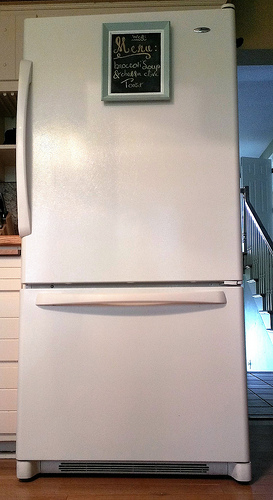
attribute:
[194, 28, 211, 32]
silver — end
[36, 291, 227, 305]
handle — white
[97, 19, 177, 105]
frame — green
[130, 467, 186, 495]
floor — dark brown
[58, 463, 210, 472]
vent — at bottom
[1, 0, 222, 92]
white cupboard —  white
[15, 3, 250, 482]
fridge — top half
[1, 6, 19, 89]
shelf — mounted up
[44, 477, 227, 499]
floor — wooden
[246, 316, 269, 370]
light — reflected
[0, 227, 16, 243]
table — wooden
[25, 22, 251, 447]
fridge — white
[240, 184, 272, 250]
rail — brown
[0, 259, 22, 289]
drawer — white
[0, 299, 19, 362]
drawer — white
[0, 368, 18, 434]
drawer — white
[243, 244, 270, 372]
stairs — white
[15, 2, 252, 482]
refrigerator — white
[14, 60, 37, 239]
handle — white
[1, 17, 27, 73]
cabinet — white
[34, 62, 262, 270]
door — white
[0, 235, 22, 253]
counter — wood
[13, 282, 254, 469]
freezer — white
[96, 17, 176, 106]
chalkboard — small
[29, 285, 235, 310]
handle — white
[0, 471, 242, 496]
wood — brown